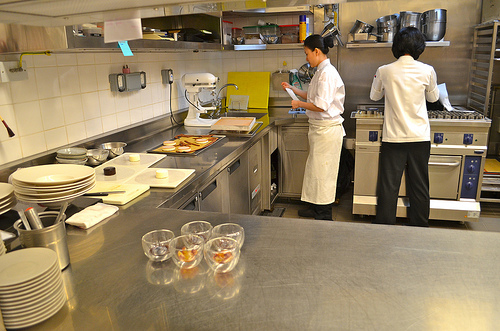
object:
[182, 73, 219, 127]
blender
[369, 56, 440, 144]
jacket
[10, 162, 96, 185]
plates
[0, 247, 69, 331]
stack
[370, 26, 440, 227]
chef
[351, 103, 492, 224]
stove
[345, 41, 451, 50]
shelf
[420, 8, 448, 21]
bowl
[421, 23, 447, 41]
bowl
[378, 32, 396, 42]
bowl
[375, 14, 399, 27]
bowl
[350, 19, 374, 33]
bowl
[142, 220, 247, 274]
bowls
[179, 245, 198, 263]
pancake syrup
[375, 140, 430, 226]
black pants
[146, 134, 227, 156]
tray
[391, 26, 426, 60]
hair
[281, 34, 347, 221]
chef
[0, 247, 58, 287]
plates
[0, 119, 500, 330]
counter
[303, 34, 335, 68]
head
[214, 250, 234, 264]
pancake syrup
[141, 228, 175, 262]
bowl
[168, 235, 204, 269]
bowl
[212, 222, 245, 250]
bowl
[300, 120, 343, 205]
apron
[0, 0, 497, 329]
kitchen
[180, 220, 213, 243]
bowl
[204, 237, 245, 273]
bowl